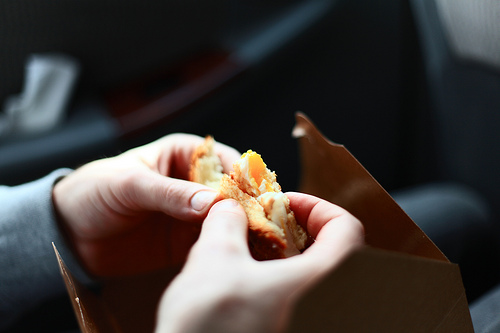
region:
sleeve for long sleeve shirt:
[1, 180, 53, 302]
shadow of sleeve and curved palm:
[51, 201, 88, 266]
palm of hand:
[71, 191, 143, 263]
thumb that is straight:
[123, 168, 213, 216]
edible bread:
[255, 211, 274, 253]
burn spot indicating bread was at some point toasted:
[220, 177, 255, 202]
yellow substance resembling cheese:
[248, 153, 263, 180]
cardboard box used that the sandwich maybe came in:
[291, 115, 373, 185]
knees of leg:
[429, 196, 479, 226]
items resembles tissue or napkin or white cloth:
[15, 54, 68, 125]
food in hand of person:
[135, 133, 374, 285]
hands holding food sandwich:
[137, 72, 327, 274]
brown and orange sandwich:
[143, 146, 302, 233]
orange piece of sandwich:
[227, 149, 267, 183]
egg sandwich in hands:
[152, 140, 289, 242]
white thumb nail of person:
[194, 190, 216, 208]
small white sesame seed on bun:
[257, 235, 284, 253]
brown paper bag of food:
[337, 200, 435, 313]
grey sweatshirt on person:
[0, 177, 60, 271]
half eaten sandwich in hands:
[175, 148, 297, 257]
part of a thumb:
[218, 215, 248, 263]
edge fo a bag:
[370, 227, 390, 247]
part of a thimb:
[211, 220, 225, 245]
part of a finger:
[254, 246, 287, 315]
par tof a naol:
[181, 193, 221, 256]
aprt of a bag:
[368, 267, 395, 326]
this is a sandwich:
[152, 150, 402, 271]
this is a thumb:
[91, 157, 242, 299]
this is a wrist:
[20, 201, 90, 266]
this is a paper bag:
[327, 241, 405, 318]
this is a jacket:
[43, 214, 66, 306]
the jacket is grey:
[37, 214, 54, 279]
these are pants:
[422, 180, 444, 237]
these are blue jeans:
[418, 167, 458, 257]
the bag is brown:
[368, 265, 414, 326]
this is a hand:
[197, 271, 233, 324]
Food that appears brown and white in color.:
[195, 137, 307, 258]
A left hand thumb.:
[126, 166, 220, 217]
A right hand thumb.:
[198, 197, 249, 254]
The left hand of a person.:
[53, 132, 241, 279]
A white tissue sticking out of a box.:
[4, 56, 79, 129]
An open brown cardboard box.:
[51, 110, 474, 332]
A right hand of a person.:
[152, 189, 364, 331]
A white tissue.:
[1, 53, 75, 133]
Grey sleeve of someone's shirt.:
[2, 167, 91, 321]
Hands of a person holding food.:
[58, 132, 363, 332]